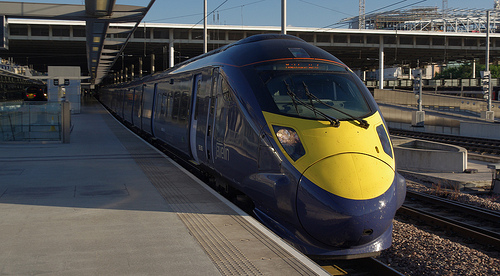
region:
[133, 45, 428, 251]
a bullet train at a station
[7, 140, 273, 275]
an empty train platform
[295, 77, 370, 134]
windshield wipers on a bullet train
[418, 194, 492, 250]
train tracks and rails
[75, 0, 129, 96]
overhead awning of a train platform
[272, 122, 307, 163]
headlight on a bullet train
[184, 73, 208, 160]
door on the side of a train car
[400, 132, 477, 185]
cement pillar in the ground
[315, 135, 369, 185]
yellow painted nose of a train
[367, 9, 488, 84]
structure being built in the background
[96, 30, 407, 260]
A long blue and yellow train.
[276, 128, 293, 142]
Small illuminated headlight.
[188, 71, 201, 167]
A lighter blue colored door on the side of the train.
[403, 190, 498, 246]
Brown tracks beside the train.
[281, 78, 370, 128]
Two sets of windshield wipers on the front of the train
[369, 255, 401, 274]
Brown track rail in front of the train.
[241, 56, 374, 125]
Large glass windshield on the front of a train.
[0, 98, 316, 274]
A large grey walkway area.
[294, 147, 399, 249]
The round part of the train that you would call the nose of the train.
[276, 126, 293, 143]
Round illuminated headlight on a train.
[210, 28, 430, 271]
The blue and yellow front of a train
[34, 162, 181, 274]
A gray concrete ground surface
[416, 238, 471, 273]
Gray gravel on the ground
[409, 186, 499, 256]
Metal railroad tracks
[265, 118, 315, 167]
A train's lit headlight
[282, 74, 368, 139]
Black windshield wipers on a train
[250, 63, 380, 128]
A train's glass windshield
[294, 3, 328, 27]
A clear blue sky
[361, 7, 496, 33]
Metal structures in the background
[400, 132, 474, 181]
A gray concrete barrier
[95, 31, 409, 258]
A blue and yellow long train.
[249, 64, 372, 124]
Front large windshield of a train.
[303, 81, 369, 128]
The right black windshield wiper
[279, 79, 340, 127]
The left black windshield wiper.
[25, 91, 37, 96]
Red tail lights in the far back.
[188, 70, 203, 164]
Blue door on the side of a train.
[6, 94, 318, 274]
Grey walkway alongside a train.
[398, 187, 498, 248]
A brown train track next to a train.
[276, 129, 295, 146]
A round illuminated headlight of a train.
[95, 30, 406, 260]
A long blue train with yellow front.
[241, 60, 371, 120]
Large glass windshield of a train.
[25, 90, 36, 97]
Two red illuminated tail lights.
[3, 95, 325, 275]
All this grey walkway to the left of the bus.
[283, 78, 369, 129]
Two black windshield wipers on the front of a train.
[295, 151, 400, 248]
the blue and yellow nose of a train.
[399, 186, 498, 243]
Brown tracks beside a train.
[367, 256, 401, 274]
Brown track in front of a train.